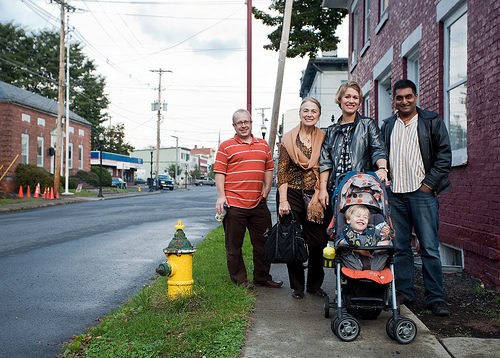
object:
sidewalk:
[243, 194, 455, 356]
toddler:
[336, 205, 391, 269]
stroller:
[326, 170, 417, 343]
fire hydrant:
[158, 217, 196, 298]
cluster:
[18, 182, 60, 199]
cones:
[18, 185, 25, 198]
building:
[345, 1, 500, 298]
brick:
[456, 186, 487, 203]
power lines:
[141, 1, 245, 62]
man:
[213, 109, 283, 287]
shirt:
[213, 134, 273, 209]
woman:
[274, 97, 329, 300]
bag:
[261, 210, 309, 266]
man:
[379, 79, 451, 314]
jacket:
[381, 108, 451, 193]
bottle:
[213, 204, 227, 222]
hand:
[420, 184, 431, 193]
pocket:
[412, 190, 437, 213]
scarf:
[282, 122, 327, 225]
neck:
[300, 124, 316, 136]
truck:
[147, 175, 174, 192]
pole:
[147, 65, 168, 184]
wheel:
[335, 317, 361, 341]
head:
[232, 109, 253, 136]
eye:
[237, 122, 241, 124]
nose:
[242, 121, 246, 127]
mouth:
[240, 128, 248, 131]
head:
[299, 96, 322, 126]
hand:
[278, 200, 291, 217]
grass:
[69, 223, 248, 357]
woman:
[319, 82, 389, 304]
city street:
[0, 186, 226, 341]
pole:
[50, 1, 70, 197]